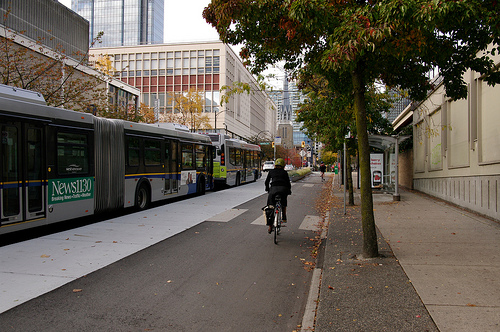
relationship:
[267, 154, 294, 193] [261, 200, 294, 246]
person riding bicycle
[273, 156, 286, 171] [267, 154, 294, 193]
hat on person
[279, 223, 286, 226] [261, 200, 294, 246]
peddle of bicycle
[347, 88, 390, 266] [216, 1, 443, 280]
trunk of tree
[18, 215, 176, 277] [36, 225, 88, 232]
sidewalk and curb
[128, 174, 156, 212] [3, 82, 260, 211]
tire on bus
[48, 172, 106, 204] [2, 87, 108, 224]
billboard on bus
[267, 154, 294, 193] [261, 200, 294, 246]
person riding bike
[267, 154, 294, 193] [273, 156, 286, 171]
person wearing helmet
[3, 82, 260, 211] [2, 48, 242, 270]
buses on street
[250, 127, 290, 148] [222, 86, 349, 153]
lights in distance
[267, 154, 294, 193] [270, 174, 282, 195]
person wearing black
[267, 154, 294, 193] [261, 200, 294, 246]
person on bicycle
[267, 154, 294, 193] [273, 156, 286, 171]
person wearing hat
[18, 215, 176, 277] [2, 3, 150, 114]
sidewalk next to building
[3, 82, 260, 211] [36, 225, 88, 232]
buses at curb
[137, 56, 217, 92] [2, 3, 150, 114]
windows on building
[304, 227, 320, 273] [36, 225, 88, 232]
leaves at curb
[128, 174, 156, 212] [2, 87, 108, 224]
wheel of bus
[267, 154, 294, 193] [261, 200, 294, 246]
man on bicycle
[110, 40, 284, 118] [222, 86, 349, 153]
building in distance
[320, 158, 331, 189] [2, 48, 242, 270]
pedestrian in street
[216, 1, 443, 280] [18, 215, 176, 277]
tree surrounded by sidewalk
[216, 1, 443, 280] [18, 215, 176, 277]
tree by sidewalk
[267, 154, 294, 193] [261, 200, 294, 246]
person on bike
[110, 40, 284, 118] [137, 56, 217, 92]
building covered in windows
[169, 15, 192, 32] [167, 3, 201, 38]
section of sky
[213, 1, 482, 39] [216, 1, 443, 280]
tops of trees